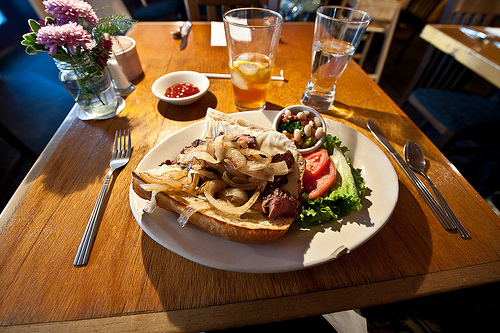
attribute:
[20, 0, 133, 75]
flowers — purple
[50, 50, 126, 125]
vase — clear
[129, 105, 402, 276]
plate — white, chipped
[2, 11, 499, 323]
table — brown, shadowed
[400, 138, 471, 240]
spoon — silver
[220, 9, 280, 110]
glass — clear, half full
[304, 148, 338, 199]
tomatoes — here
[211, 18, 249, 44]
napkin — white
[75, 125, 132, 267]
fork — silver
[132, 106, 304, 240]
sandwich — open faced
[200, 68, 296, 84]
straw — here